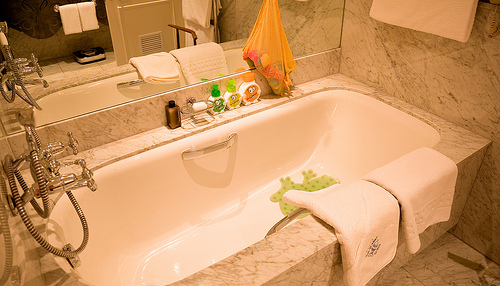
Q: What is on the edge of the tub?
A: It's towels.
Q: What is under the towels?
A: A bathtub.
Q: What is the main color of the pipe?
A: Gray.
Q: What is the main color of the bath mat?
A: Green.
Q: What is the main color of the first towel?
A: White.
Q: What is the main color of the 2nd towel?
A: White.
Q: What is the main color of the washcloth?
A: White.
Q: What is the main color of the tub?
A: White.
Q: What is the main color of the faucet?
A: Gray.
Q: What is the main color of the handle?
A: Gray.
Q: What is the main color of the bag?
A: Orange.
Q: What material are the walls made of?
A: Marble.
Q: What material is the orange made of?
A: Mesh.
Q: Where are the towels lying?
A: On tub.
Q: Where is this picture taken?
A: Bathroom.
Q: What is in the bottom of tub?
A: Bath Mat.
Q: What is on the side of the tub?
A: Handlebar.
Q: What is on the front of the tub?
A: Towels.